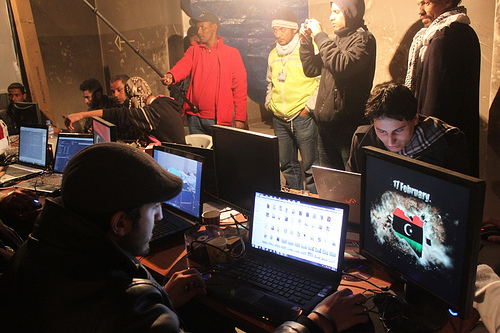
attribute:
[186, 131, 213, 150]
chair — white, plastic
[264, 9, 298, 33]
hat — grey, black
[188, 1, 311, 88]
artwork — blue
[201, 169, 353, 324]
open laptop — black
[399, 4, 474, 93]
scarf — white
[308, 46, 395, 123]
sweater — yellow, long-sleeve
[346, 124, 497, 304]
monitor — black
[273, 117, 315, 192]
jeans — blue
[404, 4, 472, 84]
scarf — white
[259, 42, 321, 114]
shirt — yellow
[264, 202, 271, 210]
icon — small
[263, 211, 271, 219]
icon — small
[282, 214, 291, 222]
icon — small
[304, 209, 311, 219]
icon — small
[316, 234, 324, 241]
icon — small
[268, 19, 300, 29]
band — white